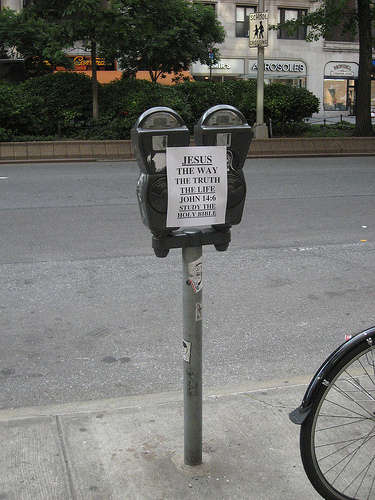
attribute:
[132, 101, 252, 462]
parking meter — dual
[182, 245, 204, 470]
pole — gray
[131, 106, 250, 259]
meters — black, pair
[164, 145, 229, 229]
sign — white, printed, christian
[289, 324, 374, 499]
bicycle wheel — black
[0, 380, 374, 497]
sidewalk — clean, gray, paved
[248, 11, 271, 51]
cossing sign — white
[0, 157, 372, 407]
street — empty, paved, grey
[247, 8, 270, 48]
sign — school crossing, white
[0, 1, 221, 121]
tree — large, full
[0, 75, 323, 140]
bushes — large, green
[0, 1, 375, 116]
store fronts — couple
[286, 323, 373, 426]
metal fender — black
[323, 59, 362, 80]
motel sign — white